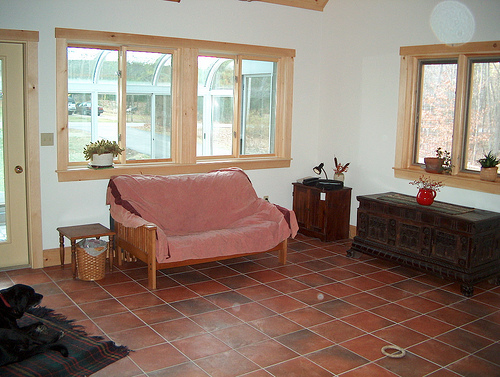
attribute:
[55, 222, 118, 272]
table — small, wood, wooden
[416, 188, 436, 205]
pot — red, white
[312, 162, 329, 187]
lamp — black, small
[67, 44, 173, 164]
window — large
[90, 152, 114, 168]
pot — white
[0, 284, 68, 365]
dog — large, black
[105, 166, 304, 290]
couch — wood, wooden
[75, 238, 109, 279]
bin — small, woven, brown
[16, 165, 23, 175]
knob — colored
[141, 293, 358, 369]
floor — rust colored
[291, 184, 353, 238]
chest — wooden, brown